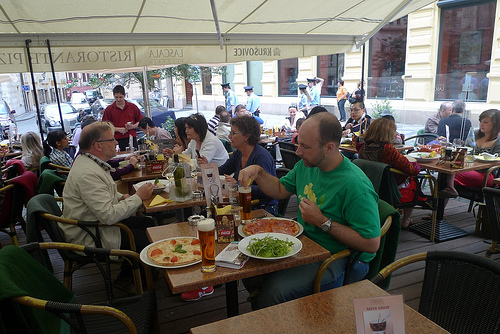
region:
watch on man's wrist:
[320, 215, 334, 232]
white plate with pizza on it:
[243, 209, 299, 236]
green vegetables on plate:
[237, 230, 297, 272]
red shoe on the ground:
[180, 285, 213, 309]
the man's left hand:
[299, 198, 323, 219]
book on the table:
[216, 234, 250, 271]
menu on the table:
[350, 295, 416, 330]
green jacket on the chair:
[0, 241, 67, 321]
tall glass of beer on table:
[200, 220, 212, 265]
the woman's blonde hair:
[362, 115, 393, 140]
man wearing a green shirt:
[278, 156, 368, 232]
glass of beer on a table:
[187, 215, 224, 272]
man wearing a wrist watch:
[319, 212, 336, 234]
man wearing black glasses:
[99, 135, 118, 145]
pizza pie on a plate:
[238, 200, 305, 253]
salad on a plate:
[247, 230, 292, 258]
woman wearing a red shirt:
[363, 140, 413, 177]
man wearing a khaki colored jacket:
[61, 160, 136, 248]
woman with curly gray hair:
[227, 112, 261, 146]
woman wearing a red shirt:
[98, 101, 146, 134]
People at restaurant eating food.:
[0, 2, 498, 332]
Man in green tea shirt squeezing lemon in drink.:
[236, 111, 385, 264]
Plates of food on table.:
[138, 205, 333, 300]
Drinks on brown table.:
[146, 180, 331, 295]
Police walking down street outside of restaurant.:
[0, 0, 495, 332]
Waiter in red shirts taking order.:
[90, 82, 148, 152]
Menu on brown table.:
[212, 237, 259, 269]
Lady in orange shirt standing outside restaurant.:
[102, 0, 497, 122]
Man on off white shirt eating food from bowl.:
[28, 120, 168, 260]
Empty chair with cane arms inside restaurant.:
[3, 0, 499, 332]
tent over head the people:
[0, 0, 367, 72]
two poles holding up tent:
[24, 36, 66, 126]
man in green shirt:
[282, 166, 383, 256]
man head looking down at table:
[293, 110, 346, 167]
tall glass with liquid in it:
[197, 218, 217, 273]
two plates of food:
[239, 214, 301, 264]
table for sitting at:
[291, 297, 378, 332]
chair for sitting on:
[0, 238, 142, 328]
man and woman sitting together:
[60, 118, 281, 200]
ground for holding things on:
[414, 220, 479, 250]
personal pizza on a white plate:
[138, 231, 213, 271]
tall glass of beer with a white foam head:
[193, 215, 220, 276]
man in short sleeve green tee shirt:
[229, 109, 388, 316]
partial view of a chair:
[365, 246, 499, 333]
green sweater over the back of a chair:
[0, 236, 152, 333]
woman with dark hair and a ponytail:
[38, 128, 75, 170]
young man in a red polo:
[98, 83, 147, 150]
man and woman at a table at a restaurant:
[52, 108, 288, 305]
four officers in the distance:
[208, 73, 338, 127]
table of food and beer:
[138, 179, 305, 281]